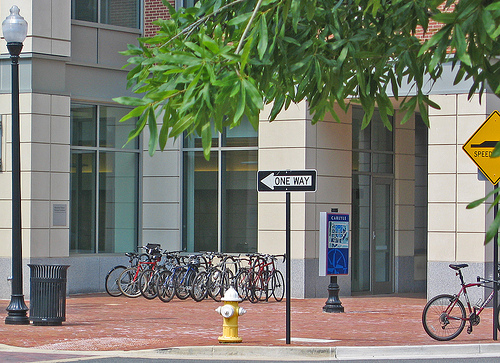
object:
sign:
[257, 170, 317, 192]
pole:
[285, 193, 292, 347]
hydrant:
[215, 286, 248, 342]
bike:
[420, 263, 499, 340]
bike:
[121, 254, 147, 298]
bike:
[246, 256, 281, 304]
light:
[2, 4, 30, 59]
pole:
[4, 43, 31, 327]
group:
[107, 242, 287, 300]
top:
[220, 286, 243, 303]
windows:
[67, 98, 137, 253]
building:
[47, 1, 158, 220]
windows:
[74, 1, 143, 37]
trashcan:
[28, 263, 68, 326]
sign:
[53, 203, 69, 230]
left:
[0, 2, 78, 360]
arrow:
[262, 171, 314, 189]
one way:
[274, 177, 309, 186]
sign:
[460, 110, 499, 185]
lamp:
[2, 4, 31, 324]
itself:
[422, 261, 499, 336]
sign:
[319, 210, 348, 277]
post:
[489, 185, 499, 340]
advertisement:
[329, 218, 349, 257]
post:
[323, 276, 342, 314]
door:
[371, 181, 391, 292]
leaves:
[111, 83, 164, 160]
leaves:
[465, 141, 499, 245]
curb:
[163, 347, 499, 358]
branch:
[161, 1, 268, 65]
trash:
[32, 274, 71, 303]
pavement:
[77, 301, 203, 340]